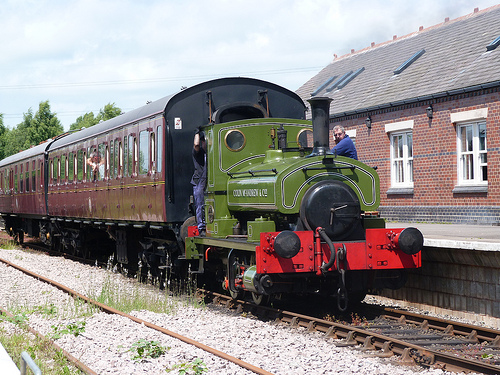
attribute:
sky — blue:
[5, 4, 499, 139]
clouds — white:
[83, 1, 436, 96]